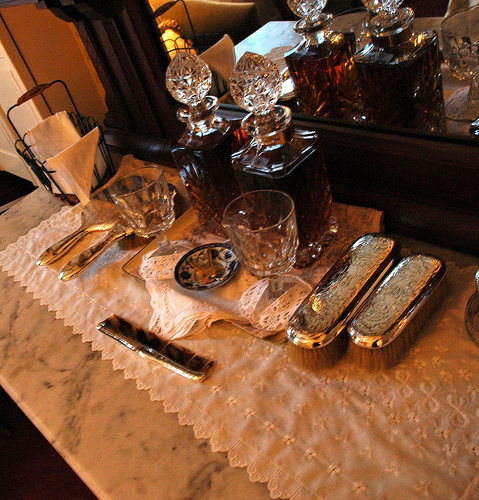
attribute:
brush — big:
[285, 227, 399, 372]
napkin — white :
[23, 109, 107, 208]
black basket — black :
[3, 74, 120, 208]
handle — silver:
[61, 218, 128, 280]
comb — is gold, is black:
[80, 312, 217, 380]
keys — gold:
[185, 247, 223, 284]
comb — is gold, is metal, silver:
[95, 313, 216, 383]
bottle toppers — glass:
[159, 61, 355, 240]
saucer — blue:
[166, 230, 232, 293]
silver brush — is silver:
[286, 232, 401, 369]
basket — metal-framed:
[8, 72, 123, 204]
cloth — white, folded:
[29, 117, 104, 203]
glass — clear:
[240, 186, 288, 268]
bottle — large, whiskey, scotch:
[227, 50, 339, 269]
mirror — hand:
[43, 168, 190, 265]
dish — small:
[173, 240, 237, 289]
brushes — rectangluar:
[282, 234, 443, 378]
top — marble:
[12, 342, 102, 454]